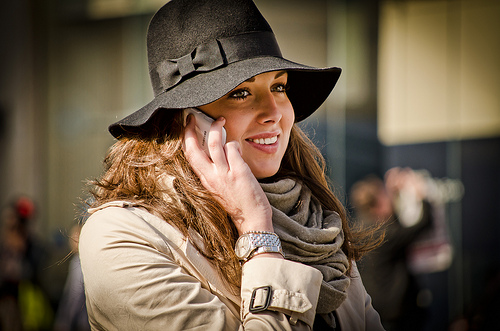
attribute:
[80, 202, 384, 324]
coat — brown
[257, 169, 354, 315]
scarf — gray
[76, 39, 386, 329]
lady — light skinned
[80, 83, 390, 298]
hair — long, unkempt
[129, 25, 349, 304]
lady — beautiful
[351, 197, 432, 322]
jacket — gray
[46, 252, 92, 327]
jacket — gray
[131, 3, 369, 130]
hat — black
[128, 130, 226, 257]
hair — long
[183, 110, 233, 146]
phone — white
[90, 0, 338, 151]
cap — black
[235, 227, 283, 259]
watch — silver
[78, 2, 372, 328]
lady — light skinned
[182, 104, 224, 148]
cell phone — white